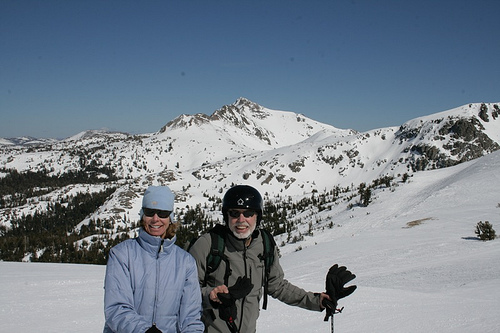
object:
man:
[191, 183, 327, 332]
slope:
[3, 195, 496, 333]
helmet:
[223, 184, 264, 219]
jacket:
[186, 226, 320, 332]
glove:
[323, 263, 355, 322]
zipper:
[235, 241, 248, 332]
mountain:
[149, 95, 335, 162]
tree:
[275, 212, 287, 232]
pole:
[324, 295, 339, 332]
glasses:
[227, 209, 256, 218]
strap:
[202, 222, 224, 278]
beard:
[225, 222, 260, 239]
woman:
[104, 184, 205, 332]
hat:
[140, 185, 176, 212]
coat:
[102, 224, 205, 332]